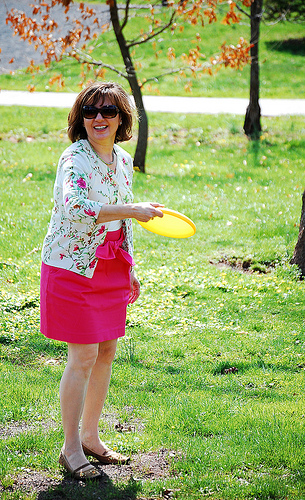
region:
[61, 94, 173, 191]
lady is wearing sunglasses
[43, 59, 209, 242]
lady holding yellow frisbee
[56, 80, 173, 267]
white sweater has pink flowers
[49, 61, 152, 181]
lady is wearing necklace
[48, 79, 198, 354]
lady wearing pink skirt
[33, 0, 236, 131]
tree has brown leaves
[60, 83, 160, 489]
lady wearing brown shoes with strap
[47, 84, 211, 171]
sidewalk behind lady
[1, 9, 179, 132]
water behind sidewalk and lady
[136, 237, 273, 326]
grass with yellow flowers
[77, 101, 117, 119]
woman's sunglasses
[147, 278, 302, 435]
green grass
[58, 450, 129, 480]
woman's brown shoes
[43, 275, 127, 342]
woman's pink skirt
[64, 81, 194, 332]
woman holding a yellow frisbee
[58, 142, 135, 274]
woman's floral jacket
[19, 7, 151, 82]
tree with brownish orange leaves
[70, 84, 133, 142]
woman's face with brown hair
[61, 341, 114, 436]
one pair of woman's legs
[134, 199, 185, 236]
woman's hand holding a yellow Frisbee disk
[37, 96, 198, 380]
woman throwing yellow frisbee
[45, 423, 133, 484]
brown MaryJane shoes with strap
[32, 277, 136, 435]
bright pink short skirt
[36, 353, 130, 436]
white female legs against green grass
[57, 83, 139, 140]
brown haired woman wearing sunglasses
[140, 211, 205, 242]
yellow frisbee being held by white female hand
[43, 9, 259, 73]
tree with orange fall foliage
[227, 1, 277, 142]
thin dark brown tree trunk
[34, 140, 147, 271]
white sweater with a pink rose pattern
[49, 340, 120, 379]
Caucasian female knees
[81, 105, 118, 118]
the ladies sunglasses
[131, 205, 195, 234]
hand holding yellow frisbee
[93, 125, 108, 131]
the ladies mouth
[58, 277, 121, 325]
pink skirt worn on woman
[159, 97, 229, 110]
sidewalk near the lawn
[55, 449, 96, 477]
ladies ankle and shoe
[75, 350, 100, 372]
one of the ladies knee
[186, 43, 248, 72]
leaves on tree branch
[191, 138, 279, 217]
area of green grass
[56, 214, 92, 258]
portion of printed jacket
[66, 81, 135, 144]
the lady is wearing sunglasses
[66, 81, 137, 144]
the lady with brown hair is smiling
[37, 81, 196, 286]
the lady is throwing a frisbee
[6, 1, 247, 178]
the tree has orange brown leaves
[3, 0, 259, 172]
the weather is changing to fall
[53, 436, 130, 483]
the lady is wearing brown flats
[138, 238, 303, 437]
the grass is green with yellow flowers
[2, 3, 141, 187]
a lake is in the park behind the lady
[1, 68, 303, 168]
a pathway goes by the lake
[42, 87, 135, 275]
the girl is wearing a flowered sweater